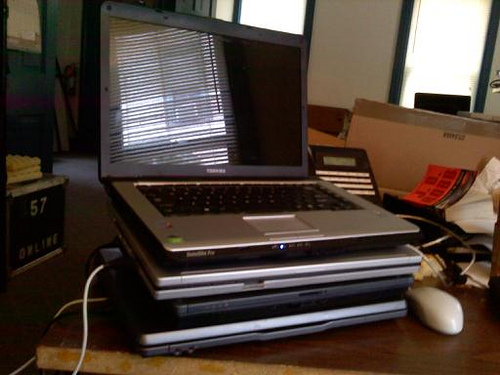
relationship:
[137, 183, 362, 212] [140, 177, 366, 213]
key on a keyboard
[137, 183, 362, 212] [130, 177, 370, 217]
key on a keyboard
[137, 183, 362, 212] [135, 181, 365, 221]
key on keyboard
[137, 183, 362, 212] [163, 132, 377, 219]
key on keyboard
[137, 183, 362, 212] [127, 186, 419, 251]
key on keyboard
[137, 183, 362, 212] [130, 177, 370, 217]
key on keyboard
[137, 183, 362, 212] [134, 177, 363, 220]
key on keyboard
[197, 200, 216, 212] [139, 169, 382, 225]
key on keyboard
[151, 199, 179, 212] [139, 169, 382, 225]
key on keyboard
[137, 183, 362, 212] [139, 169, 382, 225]
key on keyboard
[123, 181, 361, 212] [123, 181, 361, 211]
keyboard on keyboard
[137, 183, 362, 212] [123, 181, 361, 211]
key on keyboard